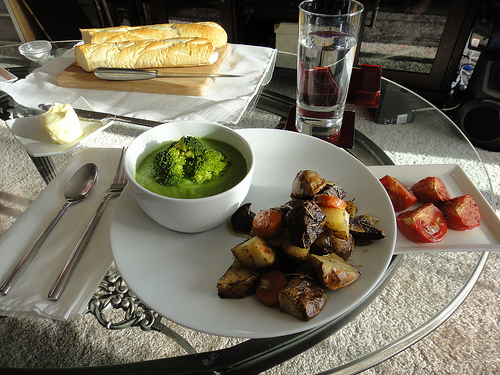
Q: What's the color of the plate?
A: White.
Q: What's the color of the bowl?
A: White.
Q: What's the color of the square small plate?
A: White.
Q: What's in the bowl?
A: Broccoli.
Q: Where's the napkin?
A: Next to plate.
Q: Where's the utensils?
A: On napkin.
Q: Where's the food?
A: On table.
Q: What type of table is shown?
A: Glass top table.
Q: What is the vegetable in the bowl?
A: Broccoli.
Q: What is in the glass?
A: Water.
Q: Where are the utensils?
A: Left of the plate.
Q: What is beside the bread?
A: Knife.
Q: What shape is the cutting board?
A: Square.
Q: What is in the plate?
A: Roasted vegetable.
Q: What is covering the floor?
A: Carpet.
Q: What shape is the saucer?
A: Square.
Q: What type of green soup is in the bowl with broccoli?
A: Broccoli soup.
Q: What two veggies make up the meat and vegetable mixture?
A: Potatoes and carrots.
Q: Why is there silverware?
A: To eat with.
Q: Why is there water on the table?
A: To drink.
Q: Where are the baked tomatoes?
A: On a plate.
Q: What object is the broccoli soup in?
A: Bowl.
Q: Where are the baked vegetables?
A: On a plate.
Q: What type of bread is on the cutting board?
A: French loaves.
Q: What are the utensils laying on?
A: Napkin.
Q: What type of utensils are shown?
A: Spoon and fork.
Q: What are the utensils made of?
A: Metal.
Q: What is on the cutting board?
A: Bread sticks.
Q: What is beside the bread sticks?
A: Knife.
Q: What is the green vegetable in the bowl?
A: Broccoli.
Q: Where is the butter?
A: Saucer beside bread.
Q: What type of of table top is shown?
A: Glass.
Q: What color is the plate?
A: White.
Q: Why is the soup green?
A: Made from broccoli.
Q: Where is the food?
A: On the table.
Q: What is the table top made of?
A: Glass.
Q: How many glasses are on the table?
A: One.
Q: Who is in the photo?
A: No one.